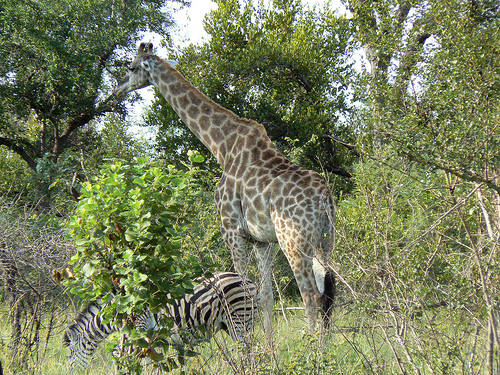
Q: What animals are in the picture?
A: Giraffe and Zebra.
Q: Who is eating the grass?
A: Zebra.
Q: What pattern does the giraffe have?
A: Spots.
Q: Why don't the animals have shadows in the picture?
A: Sky is overcast.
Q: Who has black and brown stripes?
A: Zebra.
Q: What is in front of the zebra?
A: A bush.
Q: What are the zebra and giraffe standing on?
A: Grass.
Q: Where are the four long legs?
A: On the giraffe.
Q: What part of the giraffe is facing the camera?
A: The back left hind quarters.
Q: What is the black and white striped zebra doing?
A: Grazing.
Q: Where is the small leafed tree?
A: In front of two zebras.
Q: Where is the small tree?
A: In front of the zebra.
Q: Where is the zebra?
A: Next to the giraffe.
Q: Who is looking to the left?
A: The tall giraffe.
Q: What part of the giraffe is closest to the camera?
A: The back legs.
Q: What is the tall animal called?
A: A giraffe.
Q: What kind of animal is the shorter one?
A: A zebra.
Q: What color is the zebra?
A: Black and white.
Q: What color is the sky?
A: Blue.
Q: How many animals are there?
A: 2.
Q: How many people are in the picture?
A: None.